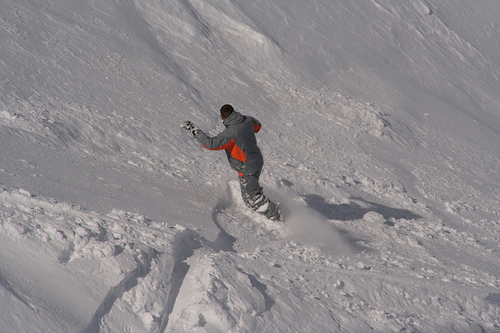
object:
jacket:
[196, 113, 265, 174]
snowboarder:
[180, 104, 282, 221]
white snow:
[0, 1, 498, 332]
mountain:
[1, 0, 500, 332]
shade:
[296, 193, 425, 226]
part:
[236, 169, 282, 221]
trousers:
[237, 169, 282, 221]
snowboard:
[230, 180, 347, 252]